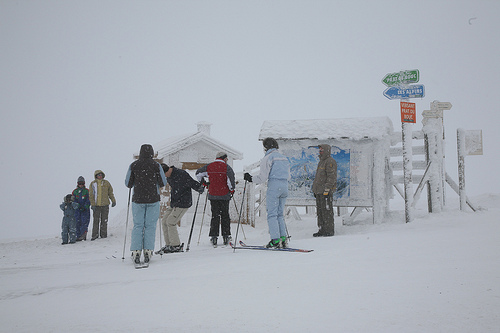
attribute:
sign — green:
[382, 68, 418, 85]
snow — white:
[1, 202, 497, 327]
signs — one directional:
[381, 71, 428, 124]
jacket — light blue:
[251, 146, 291, 183]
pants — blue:
[262, 179, 292, 246]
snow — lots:
[6, 188, 498, 331]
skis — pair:
[226, 228, 320, 257]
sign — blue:
[379, 82, 431, 102]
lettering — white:
[404, 104, 413, 114]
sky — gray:
[3, 7, 398, 121]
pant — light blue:
[261, 177, 284, 245]